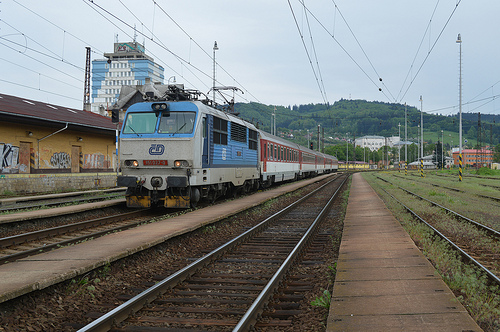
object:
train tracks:
[82, 175, 346, 329]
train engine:
[109, 93, 263, 198]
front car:
[116, 97, 261, 193]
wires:
[276, 17, 467, 121]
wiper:
[171, 122, 187, 136]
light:
[209, 37, 220, 97]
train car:
[261, 136, 303, 179]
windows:
[266, 140, 299, 158]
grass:
[410, 185, 480, 236]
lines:
[5, 5, 491, 95]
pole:
[83, 47, 92, 104]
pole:
[456, 42, 463, 149]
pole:
[418, 100, 425, 157]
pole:
[396, 125, 403, 161]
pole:
[210, 49, 216, 103]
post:
[454, 31, 466, 192]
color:
[457, 150, 464, 186]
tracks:
[0, 166, 355, 328]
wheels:
[190, 175, 276, 203]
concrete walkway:
[324, 170, 489, 330]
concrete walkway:
[0, 167, 342, 307]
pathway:
[326, 170, 473, 330]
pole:
[388, 111, 407, 178]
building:
[86, 26, 165, 116]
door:
[15, 134, 41, 187]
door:
[58, 138, 88, 178]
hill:
[285, 76, 495, 158]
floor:
[154, 106, 208, 153]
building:
[444, 145, 491, 167]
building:
[0, 91, 120, 173]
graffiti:
[0, 141, 109, 171]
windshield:
[124, 110, 198, 134]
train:
[115, 100, 340, 210]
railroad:
[4, 167, 499, 329]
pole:
[455, 150, 466, 180]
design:
[96, 58, 139, 117]